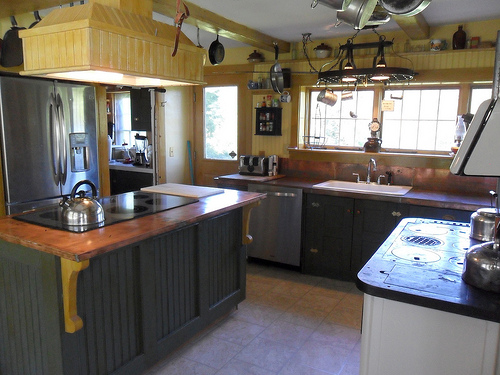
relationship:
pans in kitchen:
[176, 11, 299, 98] [23, 26, 488, 327]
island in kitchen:
[169, 171, 237, 238] [23, 26, 488, 327]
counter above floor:
[413, 175, 467, 220] [251, 276, 348, 365]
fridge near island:
[17, 83, 106, 183] [169, 171, 237, 238]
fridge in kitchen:
[17, 83, 106, 183] [23, 26, 488, 327]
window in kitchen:
[309, 81, 455, 162] [23, 26, 488, 327]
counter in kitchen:
[413, 175, 467, 220] [23, 26, 488, 327]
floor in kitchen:
[251, 276, 348, 365] [23, 26, 488, 327]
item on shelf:
[477, 38, 498, 48] [243, 44, 493, 84]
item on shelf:
[467, 35, 482, 48] [243, 44, 493, 84]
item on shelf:
[426, 38, 445, 52] [243, 44, 493, 84]